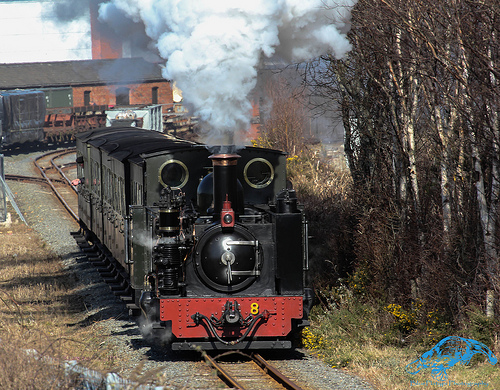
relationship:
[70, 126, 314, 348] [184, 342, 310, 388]
black train on tracks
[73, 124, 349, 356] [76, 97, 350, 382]
engine of a train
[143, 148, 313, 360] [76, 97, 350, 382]
front of a train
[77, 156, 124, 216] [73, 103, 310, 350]
windows side of train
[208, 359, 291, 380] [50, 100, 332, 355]
tracks in front of train